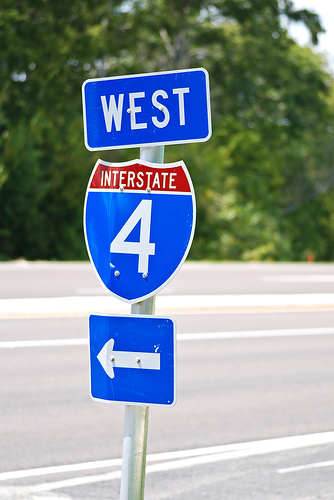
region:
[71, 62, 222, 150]
small blue directional sign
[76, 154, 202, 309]
small traffic sign for interstate four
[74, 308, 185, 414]
small blue left directional sign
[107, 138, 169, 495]
small silver traffic pole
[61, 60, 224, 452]
traffic pole with several signs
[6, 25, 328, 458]
traffic signs on interstate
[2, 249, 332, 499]
interstate road with multiple lanes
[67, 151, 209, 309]
blue and red traffic sign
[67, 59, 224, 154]
blue sign indicating west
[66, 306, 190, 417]
blue sign for left turn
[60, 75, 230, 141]
sign reads "west"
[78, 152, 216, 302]
sign reading "interstate 4"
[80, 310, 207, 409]
blue sign with white arrow pointing left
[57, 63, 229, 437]
blue and white signs on a silver post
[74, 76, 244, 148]
two screws hold the "west" sign on the post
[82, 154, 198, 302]
four screws hold the interstate 4 sign up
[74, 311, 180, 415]
two screws hold the arrow sign up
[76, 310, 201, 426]
arrow sign points to the interstate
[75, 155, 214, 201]
red portion of the sign says interstate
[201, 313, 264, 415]
empty road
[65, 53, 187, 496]
A interstate sign.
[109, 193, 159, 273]
A white number 4.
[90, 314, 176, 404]
A arrow pointing left.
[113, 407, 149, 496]
A silver metal pole.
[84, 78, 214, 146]
A sign with the word west.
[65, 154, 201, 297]
A red and blue sign.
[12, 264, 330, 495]
A gray road.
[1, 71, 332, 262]
Trees lining a roadway.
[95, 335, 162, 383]
A white arrow.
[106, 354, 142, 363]
Two bolts on a arrow.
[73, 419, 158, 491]
the pole is silver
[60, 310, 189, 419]
the arrow is pointing left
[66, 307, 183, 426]
the sign is blue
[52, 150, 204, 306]
the sign is blue and red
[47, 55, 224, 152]
the top sign says west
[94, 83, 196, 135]
the letters are white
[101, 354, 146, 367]
silver studs holding the sign to the pole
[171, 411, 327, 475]
white lines on the street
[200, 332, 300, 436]
the street is grey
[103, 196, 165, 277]
the number 4 is on the sign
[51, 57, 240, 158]
a sign that says west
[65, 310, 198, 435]
blue sign with a white arrow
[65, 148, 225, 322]
sign indicating an interstate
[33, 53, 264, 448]
group of blue and white street signs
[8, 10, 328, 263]
group of green trees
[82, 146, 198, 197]
red section with white letters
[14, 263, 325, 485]
light grey pavement with white lines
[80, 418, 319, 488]
white paint on a road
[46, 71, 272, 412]
sign that shows which way is west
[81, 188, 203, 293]
large printed number four